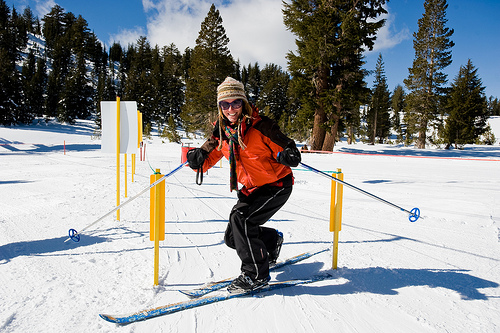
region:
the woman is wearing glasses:
[207, 58, 283, 152]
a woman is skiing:
[123, 20, 344, 247]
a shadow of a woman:
[353, 225, 499, 330]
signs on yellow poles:
[60, 60, 142, 238]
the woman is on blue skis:
[101, 245, 332, 328]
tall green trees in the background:
[409, 0, 496, 155]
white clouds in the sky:
[129, 0, 196, 51]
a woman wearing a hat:
[188, 60, 283, 152]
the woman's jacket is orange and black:
[175, 53, 300, 208]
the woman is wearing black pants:
[222, 165, 296, 299]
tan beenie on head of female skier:
[213, 69, 251, 114]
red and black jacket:
[192, 122, 299, 193]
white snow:
[44, 182, 77, 218]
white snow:
[423, 176, 490, 202]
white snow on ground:
[44, 257, 97, 307]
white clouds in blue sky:
[106, 3, 139, 32]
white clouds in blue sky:
[151, 13, 203, 43]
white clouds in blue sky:
[221, 11, 269, 44]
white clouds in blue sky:
[378, 7, 408, 89]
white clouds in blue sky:
[453, 11, 481, 63]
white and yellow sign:
[92, 91, 134, 154]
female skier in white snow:
[181, 71, 290, 286]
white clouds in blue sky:
[457, 21, 484, 53]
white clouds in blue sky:
[361, 10, 411, 72]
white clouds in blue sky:
[227, 10, 268, 55]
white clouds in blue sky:
[146, 16, 168, 41]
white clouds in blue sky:
[100, 12, 135, 36]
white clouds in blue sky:
[110, 0, 182, 46]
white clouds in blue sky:
[458, 7, 490, 66]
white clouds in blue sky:
[379, 6, 417, 55]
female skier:
[178, 67, 327, 287]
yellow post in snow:
[140, 166, 180, 293]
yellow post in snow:
[308, 164, 354, 279]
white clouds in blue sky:
[93, 4, 129, 40]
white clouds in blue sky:
[148, 17, 173, 34]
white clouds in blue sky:
[237, 21, 276, 51]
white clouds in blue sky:
[380, 6, 434, 40]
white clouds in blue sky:
[372, 55, 397, 85]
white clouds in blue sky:
[454, 14, 487, 40]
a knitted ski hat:
[215, 74, 248, 101]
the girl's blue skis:
[97, 237, 338, 328]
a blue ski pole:
[276, 145, 428, 226]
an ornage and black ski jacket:
[190, 113, 297, 195]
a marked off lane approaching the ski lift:
[137, 134, 359, 290]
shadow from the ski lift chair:
[2, 203, 144, 273]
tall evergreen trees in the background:
[277, 0, 388, 158]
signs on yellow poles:
[97, 96, 144, 223]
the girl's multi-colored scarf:
[205, 109, 267, 144]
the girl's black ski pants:
[224, 174, 299, 292]